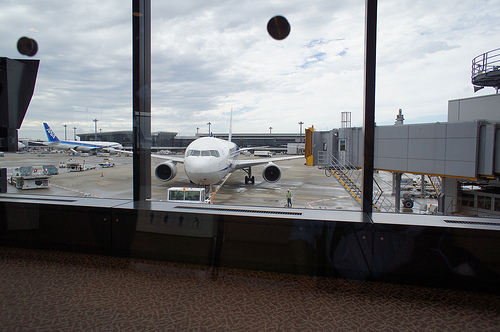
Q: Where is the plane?
A: On the other side of window.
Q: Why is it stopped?
A: It's loading.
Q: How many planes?
A: 2.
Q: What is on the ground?
A: Plane.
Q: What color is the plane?
A: White.